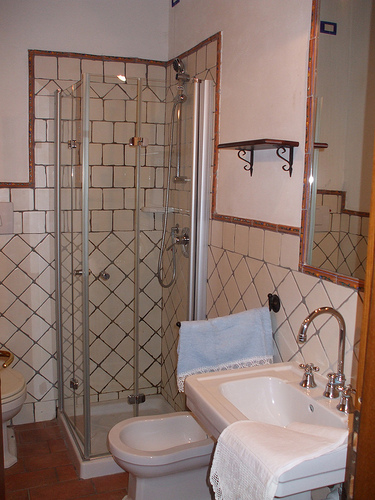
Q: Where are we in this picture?
A: Bathroom.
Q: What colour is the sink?
A: White.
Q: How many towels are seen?
A: 2.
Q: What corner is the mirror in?
A: Top right.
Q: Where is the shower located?
A: Back.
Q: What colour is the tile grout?
A: Black.